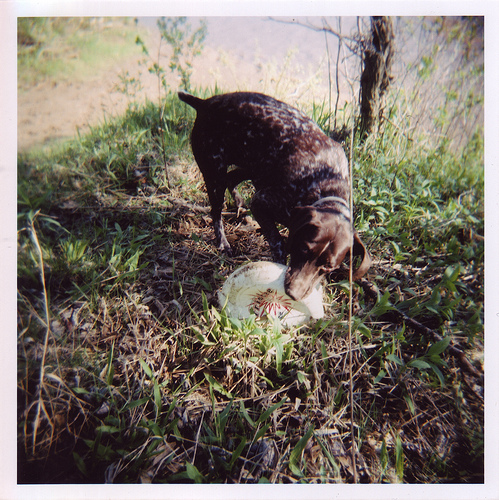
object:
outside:
[15, 17, 172, 358]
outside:
[370, 41, 484, 328]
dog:
[175, 88, 374, 304]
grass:
[397, 275, 445, 336]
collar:
[308, 194, 353, 209]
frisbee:
[215, 259, 326, 338]